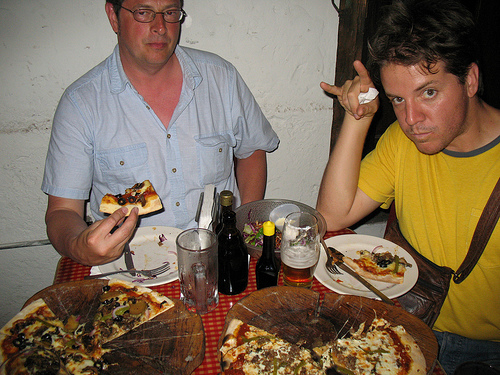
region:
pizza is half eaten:
[100, 181, 161, 214]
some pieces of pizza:
[0, 279, 173, 374]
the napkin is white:
[358, 86, 378, 103]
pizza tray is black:
[227, 289, 439, 374]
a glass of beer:
[281, 210, 320, 285]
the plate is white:
[313, 233, 419, 301]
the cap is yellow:
[262, 220, 273, 232]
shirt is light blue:
[44, 45, 281, 230]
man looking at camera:
[378, 8, 479, 154]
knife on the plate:
[327, 252, 389, 302]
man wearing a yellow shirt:
[410, 179, 481, 221]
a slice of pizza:
[108, 288, 146, 322]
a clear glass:
[179, 241, 218, 299]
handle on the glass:
[194, 266, 207, 306]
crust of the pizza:
[150, 199, 162, 212]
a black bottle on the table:
[216, 198, 247, 288]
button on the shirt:
[165, 167, 179, 177]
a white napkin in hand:
[358, 88, 380, 106]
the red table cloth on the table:
[201, 307, 219, 327]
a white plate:
[321, 269, 333, 286]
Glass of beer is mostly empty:
[279, 210, 321, 287]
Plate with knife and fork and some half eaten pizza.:
[315, 232, 420, 300]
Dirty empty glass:
[176, 227, 218, 317]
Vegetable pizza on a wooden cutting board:
[2, 272, 207, 373]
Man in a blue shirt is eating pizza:
[38, 1, 275, 276]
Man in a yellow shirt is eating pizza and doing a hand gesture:
[313, 9, 498, 373]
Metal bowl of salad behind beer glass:
[226, 195, 324, 269]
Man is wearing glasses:
[43, 0, 273, 290]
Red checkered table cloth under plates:
[39, 246, 401, 372]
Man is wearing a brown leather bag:
[317, 16, 498, 372]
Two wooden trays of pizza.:
[0, 272, 439, 373]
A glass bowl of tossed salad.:
[237, 198, 290, 249]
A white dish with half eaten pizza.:
[326, 222, 420, 297]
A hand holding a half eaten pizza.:
[73, 179, 165, 261]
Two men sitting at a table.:
[1, 1, 498, 373]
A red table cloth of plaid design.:
[198, 312, 223, 373]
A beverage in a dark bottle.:
[212, 177, 250, 294]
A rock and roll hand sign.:
[312, 59, 382, 122]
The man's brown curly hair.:
[370, 18, 490, 63]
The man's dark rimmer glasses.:
[125, 3, 187, 26]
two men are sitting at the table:
[68, 5, 475, 373]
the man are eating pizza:
[44, 176, 399, 306]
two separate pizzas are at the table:
[11, 273, 425, 372]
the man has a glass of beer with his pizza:
[286, 211, 326, 284]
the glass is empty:
[167, 225, 221, 311]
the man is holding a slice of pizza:
[91, 181, 174, 225]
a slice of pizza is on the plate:
[331, 240, 412, 283]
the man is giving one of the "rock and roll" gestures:
[311, 56, 388, 126]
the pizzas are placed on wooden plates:
[17, 270, 436, 374]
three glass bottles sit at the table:
[215, 183, 284, 298]